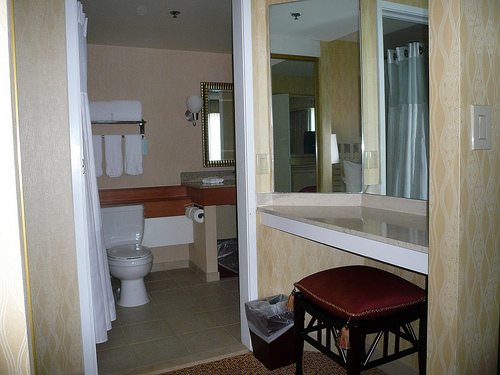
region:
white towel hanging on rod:
[84, 133, 111, 195]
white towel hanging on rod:
[99, 133, 133, 201]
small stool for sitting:
[273, 246, 438, 373]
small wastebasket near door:
[247, 283, 312, 374]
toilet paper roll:
[185, 203, 210, 228]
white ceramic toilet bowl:
[92, 195, 179, 324]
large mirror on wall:
[267, 5, 369, 218]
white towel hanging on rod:
[85, 129, 115, 181]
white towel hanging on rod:
[105, 129, 132, 193]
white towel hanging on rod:
[125, 137, 154, 184]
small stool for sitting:
[282, 242, 412, 363]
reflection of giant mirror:
[288, 32, 355, 194]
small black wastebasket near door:
[244, 284, 309, 374]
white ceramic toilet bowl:
[96, 191, 175, 324]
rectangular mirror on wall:
[199, 73, 246, 180]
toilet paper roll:
[185, 202, 201, 227]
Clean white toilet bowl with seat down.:
[94, 203, 159, 310]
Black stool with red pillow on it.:
[285, 253, 430, 373]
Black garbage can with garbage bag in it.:
[252, 290, 307, 368]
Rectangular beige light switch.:
[467, 103, 496, 156]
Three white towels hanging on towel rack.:
[85, 131, 145, 180]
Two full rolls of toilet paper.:
[180, 203, 204, 224]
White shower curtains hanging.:
[74, 1, 119, 341]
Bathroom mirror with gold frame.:
[198, 78, 240, 167]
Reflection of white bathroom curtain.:
[384, 46, 430, 201]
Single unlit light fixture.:
[184, 91, 204, 125]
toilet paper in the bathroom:
[181, 205, 206, 222]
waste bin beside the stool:
[241, 285, 306, 355]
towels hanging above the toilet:
[95, 126, 161, 178]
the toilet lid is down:
[105, 235, 145, 260]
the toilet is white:
[95, 200, 171, 305]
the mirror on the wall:
[195, 75, 236, 172]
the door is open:
[65, 5, 100, 372]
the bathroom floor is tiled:
[120, 280, 245, 355]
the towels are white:
[90, 135, 143, 177]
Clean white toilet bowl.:
[97, 202, 159, 309]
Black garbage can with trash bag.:
[240, 285, 306, 370]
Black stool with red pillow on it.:
[289, 253, 424, 373]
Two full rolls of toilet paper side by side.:
[178, 201, 210, 227]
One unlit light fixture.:
[179, 89, 208, 130]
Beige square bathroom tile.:
[103, 263, 238, 372]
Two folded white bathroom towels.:
[79, 96, 146, 122]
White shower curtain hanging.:
[78, 61, 108, 351]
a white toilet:
[106, 208, 152, 303]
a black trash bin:
[251, 296, 301, 368]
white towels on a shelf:
[90, 102, 141, 118]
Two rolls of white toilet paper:
[182, 205, 208, 227]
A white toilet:
[100, 203, 158, 310]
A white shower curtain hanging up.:
[77, 3, 129, 348]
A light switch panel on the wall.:
[469, 103, 491, 153]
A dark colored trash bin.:
[247, 298, 307, 365]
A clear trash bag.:
[241, 293, 295, 341]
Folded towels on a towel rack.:
[87, 98, 151, 125]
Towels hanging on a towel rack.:
[93, 126, 144, 185]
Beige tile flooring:
[102, 258, 255, 373]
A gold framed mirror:
[201, 78, 239, 172]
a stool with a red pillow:
[290, 263, 427, 374]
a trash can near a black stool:
[243, 293, 308, 372]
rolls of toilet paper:
[183, 203, 208, 224]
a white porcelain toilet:
[96, 203, 156, 309]